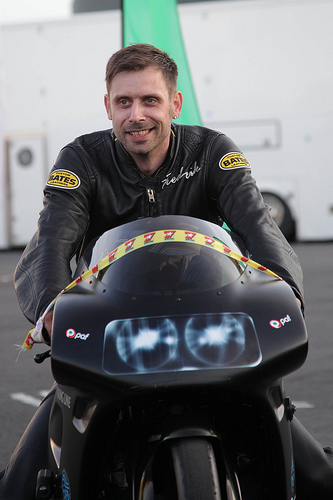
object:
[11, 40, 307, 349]
man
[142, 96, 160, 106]
eye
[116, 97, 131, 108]
eye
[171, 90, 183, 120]
ear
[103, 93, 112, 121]
ear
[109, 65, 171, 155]
face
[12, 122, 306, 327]
coat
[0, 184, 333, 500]
bike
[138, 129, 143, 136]
teeth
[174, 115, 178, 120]
earring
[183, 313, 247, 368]
headlight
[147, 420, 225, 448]
guard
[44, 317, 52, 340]
finger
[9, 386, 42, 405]
line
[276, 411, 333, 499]
trouser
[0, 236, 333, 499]
road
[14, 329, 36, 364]
rope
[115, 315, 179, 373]
headlights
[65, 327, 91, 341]
logo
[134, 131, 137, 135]
teeth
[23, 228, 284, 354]
ribbon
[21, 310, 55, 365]
gear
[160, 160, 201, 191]
racer id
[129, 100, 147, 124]
nose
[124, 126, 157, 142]
mouth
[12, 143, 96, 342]
arm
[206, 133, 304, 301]
arm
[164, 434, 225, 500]
wheel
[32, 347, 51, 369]
brake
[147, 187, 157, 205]
zipper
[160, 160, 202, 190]
writing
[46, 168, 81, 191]
patch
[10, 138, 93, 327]
sleeve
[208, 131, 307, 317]
sleeve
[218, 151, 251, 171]
patch